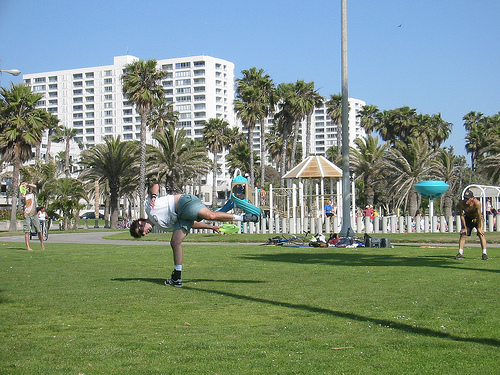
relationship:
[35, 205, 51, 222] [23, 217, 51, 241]
woman riding bicycle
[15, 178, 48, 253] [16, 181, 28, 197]
man throwing frisbee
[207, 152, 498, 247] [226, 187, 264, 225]
playground with slide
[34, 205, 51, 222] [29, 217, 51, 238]
woman riding bicycle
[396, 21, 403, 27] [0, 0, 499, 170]
bird in sky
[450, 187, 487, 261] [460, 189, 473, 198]
guy in baseball cap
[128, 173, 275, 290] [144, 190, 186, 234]
man in shirt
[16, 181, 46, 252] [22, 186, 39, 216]
man in shirt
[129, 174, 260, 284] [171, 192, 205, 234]
man in shorts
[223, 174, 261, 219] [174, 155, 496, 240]
slide in playground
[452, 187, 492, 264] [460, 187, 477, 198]
guy wearing baseball cap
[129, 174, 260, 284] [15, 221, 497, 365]
man on ground